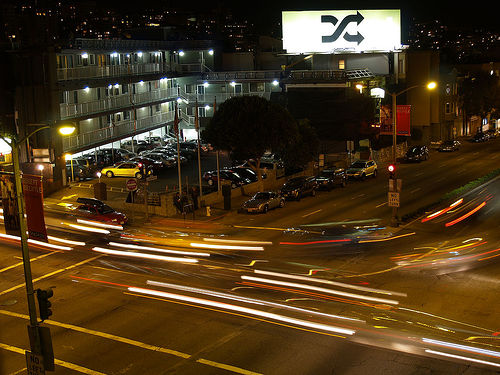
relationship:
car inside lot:
[101, 159, 153, 179] [66, 134, 302, 199]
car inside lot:
[142, 153, 176, 169] [66, 134, 302, 199]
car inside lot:
[202, 169, 251, 189] [66, 134, 302, 199]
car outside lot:
[242, 190, 286, 213] [66, 134, 302, 199]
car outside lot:
[344, 158, 379, 181] [66, 134, 302, 199]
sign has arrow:
[282, 9, 401, 54] [321, 11, 364, 43]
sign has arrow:
[282, 9, 401, 54] [343, 30, 365, 44]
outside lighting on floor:
[81, 53, 90, 59] [57, 49, 215, 81]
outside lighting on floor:
[83, 86, 92, 93] [60, 75, 201, 104]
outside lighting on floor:
[228, 81, 237, 87] [178, 77, 282, 104]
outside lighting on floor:
[85, 118, 94, 122] [63, 100, 175, 150]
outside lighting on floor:
[203, 104, 211, 110] [177, 98, 220, 127]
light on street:
[76, 217, 124, 231] [1, 134, 500, 374]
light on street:
[189, 241, 264, 251] [1, 134, 500, 374]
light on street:
[108, 241, 210, 258] [1, 134, 500, 374]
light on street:
[253, 268, 407, 298] [1, 134, 500, 374]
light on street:
[47, 234, 86, 246] [1, 134, 500, 374]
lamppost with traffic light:
[9, 138, 41, 355] [36, 287, 54, 319]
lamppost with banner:
[9, 138, 41, 355] [21, 173, 50, 242]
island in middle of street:
[372, 169, 499, 237] [1, 134, 500, 374]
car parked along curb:
[242, 190, 286, 213] [201, 130, 499, 220]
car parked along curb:
[344, 158, 379, 181] [201, 130, 499, 220]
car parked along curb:
[314, 165, 348, 193] [201, 130, 499, 220]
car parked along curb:
[402, 143, 429, 163] [201, 130, 499, 220]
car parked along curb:
[437, 139, 462, 152] [201, 130, 499, 220]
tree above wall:
[199, 94, 294, 192] [196, 169, 310, 208]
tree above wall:
[272, 115, 320, 176] [196, 169, 310, 208]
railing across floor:
[58, 62, 162, 80] [57, 49, 215, 81]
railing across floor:
[59, 87, 179, 118] [60, 75, 201, 104]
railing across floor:
[178, 86, 271, 102] [178, 77, 282, 104]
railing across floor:
[62, 109, 177, 153] [63, 100, 175, 150]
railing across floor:
[179, 108, 196, 125] [177, 98, 220, 127]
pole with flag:
[174, 100, 182, 194] [174, 103, 180, 137]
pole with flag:
[195, 96, 203, 197] [194, 98, 200, 131]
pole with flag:
[214, 94, 221, 193] [214, 98, 217, 113]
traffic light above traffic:
[36, 287, 54, 319] [1, 178, 500, 368]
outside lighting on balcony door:
[81, 53, 90, 59] [83, 59, 89, 67]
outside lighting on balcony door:
[83, 86, 92, 93] [96, 86, 102, 100]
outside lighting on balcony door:
[85, 118, 94, 122] [76, 121, 81, 134]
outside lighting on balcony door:
[228, 81, 237, 87] [233, 82, 243, 94]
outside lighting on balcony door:
[203, 104, 211, 110] [197, 106, 206, 117]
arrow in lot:
[58, 194, 78, 201] [66, 134, 302, 199]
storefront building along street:
[438, 66, 460, 146] [1, 134, 500, 374]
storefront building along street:
[453, 77, 464, 141] [1, 134, 500, 374]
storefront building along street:
[435, 61, 462, 145] [1, 134, 500, 374]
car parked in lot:
[101, 159, 153, 179] [66, 134, 302, 199]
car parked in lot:
[142, 153, 176, 169] [66, 134, 302, 199]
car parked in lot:
[202, 169, 251, 189] [66, 134, 302, 199]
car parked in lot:
[222, 165, 265, 180] [66, 134, 302, 199]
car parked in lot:
[155, 145, 180, 155] [66, 134, 302, 199]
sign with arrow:
[282, 9, 401, 54] [321, 11, 364, 43]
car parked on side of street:
[242, 190, 286, 213] [1, 134, 500, 374]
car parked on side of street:
[314, 165, 348, 193] [1, 134, 500, 374]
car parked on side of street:
[402, 143, 429, 163] [1, 134, 500, 374]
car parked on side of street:
[437, 139, 462, 152] [1, 134, 500, 374]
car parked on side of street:
[279, 174, 318, 202] [1, 134, 500, 374]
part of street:
[1, 203, 154, 295] [1, 134, 500, 374]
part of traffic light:
[36, 287, 53, 300] [36, 287, 54, 319]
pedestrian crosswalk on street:
[1, 230, 121, 293] [1, 134, 500, 374]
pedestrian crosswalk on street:
[0, 309, 265, 374] [1, 134, 500, 374]